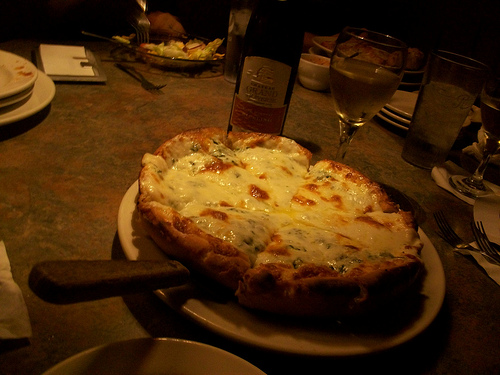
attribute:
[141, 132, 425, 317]
pizza — shadowed, cheesy, small, plated, crusted, sauced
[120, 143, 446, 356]
plate — white, small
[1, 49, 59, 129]
plates — stacked, dirty, tabled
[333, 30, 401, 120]
wine — white, bottled, clear, glassed, present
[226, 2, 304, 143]
bottle — labeled, tabled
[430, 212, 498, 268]
forks — pronged, silver, touching, standing, tabled, tipped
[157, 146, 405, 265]
cheese — melted, white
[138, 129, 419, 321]
crust — thick, brown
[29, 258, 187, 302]
handle — wooden, present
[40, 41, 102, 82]
paper — white, present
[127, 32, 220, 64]
salad — mixed, bowled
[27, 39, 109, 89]
holder — silver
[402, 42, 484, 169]
cup — clear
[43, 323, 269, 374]
bowl — white